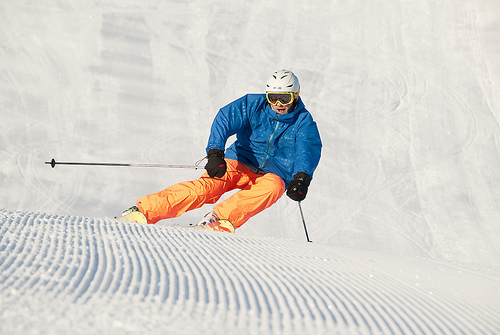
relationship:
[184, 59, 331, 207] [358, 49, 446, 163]
person skiing on snow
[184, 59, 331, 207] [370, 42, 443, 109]
person skiing on hill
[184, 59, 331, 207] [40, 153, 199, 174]
person holding poles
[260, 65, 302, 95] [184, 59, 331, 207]
helmet on person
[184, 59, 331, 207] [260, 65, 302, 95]
person wearing helmet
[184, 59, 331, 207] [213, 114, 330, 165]
person wearing a jacket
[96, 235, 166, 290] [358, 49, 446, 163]
ridges through snow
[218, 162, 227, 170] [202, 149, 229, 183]
spot on top of glove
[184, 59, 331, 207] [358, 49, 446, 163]
person skiing in snow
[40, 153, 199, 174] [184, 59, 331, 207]
pole for skiier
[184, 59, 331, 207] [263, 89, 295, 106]
person wearing goggles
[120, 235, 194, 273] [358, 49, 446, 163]
tracks through snow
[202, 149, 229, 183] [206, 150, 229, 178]
glove on left hand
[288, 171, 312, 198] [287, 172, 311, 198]
glove on right hand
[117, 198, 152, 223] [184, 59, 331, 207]
foot attached to person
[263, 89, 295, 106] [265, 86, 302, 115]
goggles cover face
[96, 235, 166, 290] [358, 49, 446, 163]
trail through snow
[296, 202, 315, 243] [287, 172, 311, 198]
ski pole in right hand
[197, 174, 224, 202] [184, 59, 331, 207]
knee of a skier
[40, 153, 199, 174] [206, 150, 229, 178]
pole in skiers hand